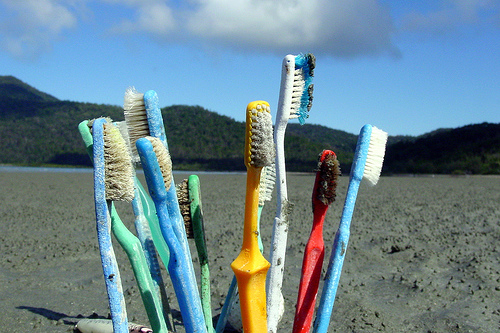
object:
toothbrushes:
[78, 50, 388, 329]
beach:
[1, 164, 498, 329]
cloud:
[106, 0, 403, 60]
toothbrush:
[87, 115, 142, 323]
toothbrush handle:
[107, 206, 167, 326]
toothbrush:
[231, 100, 277, 329]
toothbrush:
[269, 53, 318, 326]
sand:
[306, 53, 313, 101]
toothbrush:
[290, 147, 339, 330]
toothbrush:
[315, 127, 393, 329]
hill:
[1, 77, 496, 169]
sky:
[1, 0, 494, 138]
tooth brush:
[230, 98, 277, 328]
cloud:
[128, 5, 410, 64]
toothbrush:
[233, 100, 273, 327]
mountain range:
[0, 74, 495, 173]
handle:
[230, 170, 273, 330]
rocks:
[386, 242, 419, 294]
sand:
[0, 163, 494, 329]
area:
[0, 161, 494, 329]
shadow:
[13, 298, 112, 329]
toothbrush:
[300, 147, 345, 330]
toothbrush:
[323, 122, 388, 329]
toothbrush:
[90, 108, 152, 326]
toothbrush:
[170, 159, 235, 329]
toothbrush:
[232, 94, 288, 330]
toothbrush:
[239, 93, 279, 330]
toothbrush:
[249, 91, 289, 331]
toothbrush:
[236, 97, 286, 330]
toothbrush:
[89, 107, 139, 330]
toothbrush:
[132, 125, 202, 330]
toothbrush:
[122, 82, 216, 307]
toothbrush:
[309, 120, 385, 330]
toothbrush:
[298, 144, 332, 328]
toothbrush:
[276, 40, 318, 330]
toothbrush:
[80, 123, 174, 328]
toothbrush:
[100, 116, 216, 326]